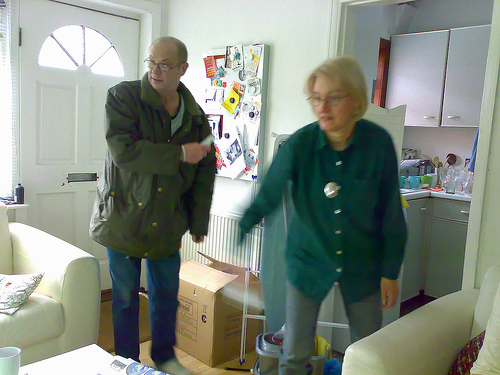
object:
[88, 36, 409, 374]
couple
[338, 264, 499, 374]
couch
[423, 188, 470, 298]
cabinets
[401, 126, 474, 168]
wall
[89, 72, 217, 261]
jacket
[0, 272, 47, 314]
pillow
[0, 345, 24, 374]
cup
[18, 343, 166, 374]
table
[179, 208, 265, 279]
rack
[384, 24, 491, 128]
cabinets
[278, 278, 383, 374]
pants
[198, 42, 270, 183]
wall board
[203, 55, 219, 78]
note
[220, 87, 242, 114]
note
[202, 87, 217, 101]
note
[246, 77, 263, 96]
note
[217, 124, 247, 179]
note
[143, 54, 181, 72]
eye glasses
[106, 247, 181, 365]
jeans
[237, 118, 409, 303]
shirt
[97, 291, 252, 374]
floor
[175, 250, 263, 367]
box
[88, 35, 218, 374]
guy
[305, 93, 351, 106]
glasses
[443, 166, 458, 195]
glasses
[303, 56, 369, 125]
hair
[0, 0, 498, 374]
house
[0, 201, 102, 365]
couch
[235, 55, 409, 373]
lady